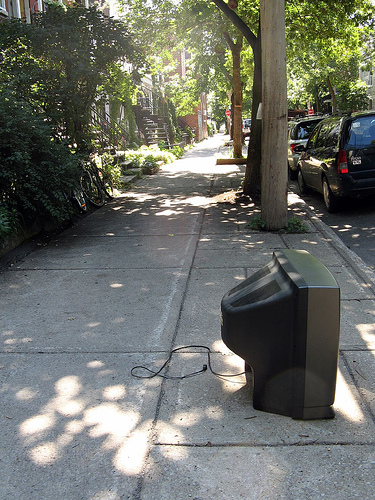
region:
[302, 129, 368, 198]
the car is black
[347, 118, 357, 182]
the car is black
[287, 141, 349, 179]
the car is black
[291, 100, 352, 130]
the car is black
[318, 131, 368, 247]
the car is black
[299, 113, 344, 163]
the car is black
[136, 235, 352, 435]
the television on the roadside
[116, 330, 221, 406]
the black colored cable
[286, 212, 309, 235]
the green colored grass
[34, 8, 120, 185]
the green colored trees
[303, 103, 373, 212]
the black colored car parked on the road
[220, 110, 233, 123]
the red colored sign board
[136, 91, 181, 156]
the iron steps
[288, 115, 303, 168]
the grey colored car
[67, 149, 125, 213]
the cycle parked on the road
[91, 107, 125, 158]
the iron rods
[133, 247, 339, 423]
an older style tv is on the curb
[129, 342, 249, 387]
the electric cord of the tv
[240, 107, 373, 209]
cars are parked on the side of the road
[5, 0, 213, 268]
houses line the street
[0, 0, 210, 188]
the townhouses are next to each other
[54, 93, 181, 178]
stair cases lead into the houses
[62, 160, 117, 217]
bikes are parked on the sidewalk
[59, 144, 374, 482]
the trees shade the sidewalk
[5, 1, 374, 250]
it is summertime in the city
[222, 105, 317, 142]
stop signs are at the end of street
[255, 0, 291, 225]
a tree on the side of a road.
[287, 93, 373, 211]
a parked black car.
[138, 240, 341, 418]
a busted 90's style TV.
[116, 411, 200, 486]
a patch of sunlight.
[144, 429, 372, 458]
a crack in a sidewalk.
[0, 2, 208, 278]
a nice neighborhood.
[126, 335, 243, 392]
a power cord for an old TV.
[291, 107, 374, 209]
a parked car.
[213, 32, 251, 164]
a tree on a sidewalk.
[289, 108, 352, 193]
these are cars parked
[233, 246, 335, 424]
this is a tv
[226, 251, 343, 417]
the tv is on the floor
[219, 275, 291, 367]
the back is black in color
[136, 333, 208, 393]
this is a wire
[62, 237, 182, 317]
this is a pavement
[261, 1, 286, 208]
this is a pole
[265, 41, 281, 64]
the pole is wooden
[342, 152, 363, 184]
the car is black in color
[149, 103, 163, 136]
this is a staircase